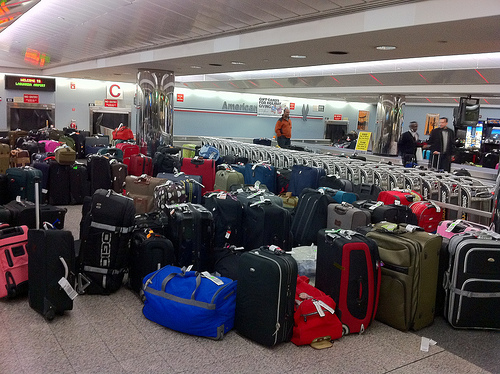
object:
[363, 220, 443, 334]
luggage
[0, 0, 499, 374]
airport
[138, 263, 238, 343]
duffel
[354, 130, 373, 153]
sign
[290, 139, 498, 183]
carousel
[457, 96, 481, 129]
monitor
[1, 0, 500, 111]
ceiling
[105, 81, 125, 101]
sign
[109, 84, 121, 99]
letter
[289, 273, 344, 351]
bag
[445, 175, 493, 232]
carts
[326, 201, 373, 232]
suitcase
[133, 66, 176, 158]
pole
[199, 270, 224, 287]
tag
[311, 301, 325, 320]
tag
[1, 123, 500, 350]
group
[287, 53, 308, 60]
lights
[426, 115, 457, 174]
man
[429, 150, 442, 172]
handle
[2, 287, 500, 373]
floor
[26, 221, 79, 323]
bag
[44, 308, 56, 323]
wheels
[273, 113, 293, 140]
coat